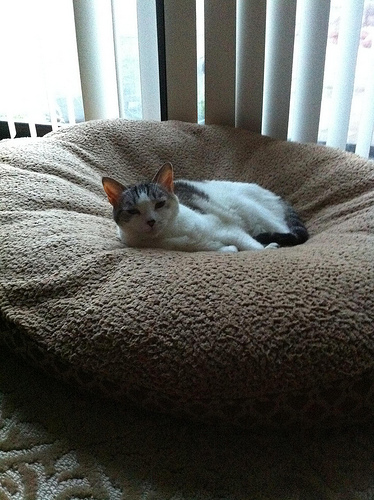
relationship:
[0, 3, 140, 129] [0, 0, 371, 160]
sunlight coming through window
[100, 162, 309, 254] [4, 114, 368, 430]
cat on bed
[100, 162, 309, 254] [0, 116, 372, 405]
cat on pet pillow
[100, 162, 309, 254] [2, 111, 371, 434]
cat in seat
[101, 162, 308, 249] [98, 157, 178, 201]
cat has ears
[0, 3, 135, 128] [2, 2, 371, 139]
sunlight shining through blinds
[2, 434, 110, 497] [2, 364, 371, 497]
design in carpet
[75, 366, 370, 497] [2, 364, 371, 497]
shadow on carpet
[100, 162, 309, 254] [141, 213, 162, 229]
cat has nose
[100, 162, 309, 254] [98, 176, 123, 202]
cat has ear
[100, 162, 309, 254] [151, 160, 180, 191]
cat has ear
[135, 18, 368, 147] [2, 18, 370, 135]
vertical blinds on window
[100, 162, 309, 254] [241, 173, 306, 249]
cat has back end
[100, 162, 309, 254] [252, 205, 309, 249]
cat has tail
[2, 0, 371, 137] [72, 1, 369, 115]
window has blinds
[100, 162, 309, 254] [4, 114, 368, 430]
cat resting in bed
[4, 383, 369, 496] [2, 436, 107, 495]
carpet with pattern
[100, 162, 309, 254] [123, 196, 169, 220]
cat has eyes